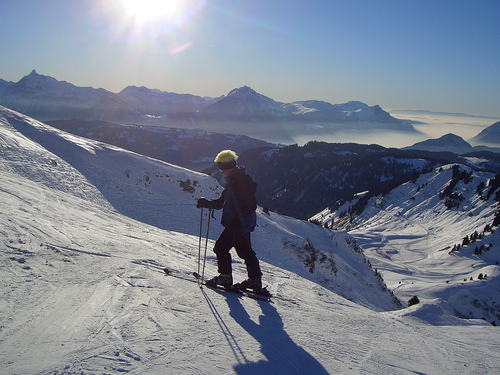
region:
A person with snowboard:
[122, 144, 298, 326]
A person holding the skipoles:
[188, 214, 211, 286]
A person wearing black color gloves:
[192, 190, 220, 215]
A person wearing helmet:
[213, 144, 235, 170]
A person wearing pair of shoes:
[209, 268, 277, 293]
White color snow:
[33, 207, 127, 315]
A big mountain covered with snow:
[319, 106, 486, 266]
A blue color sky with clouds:
[300, 22, 480, 65]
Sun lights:
[115, 0, 221, 42]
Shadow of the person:
[203, 298, 320, 370]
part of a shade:
[248, 306, 273, 356]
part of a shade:
[266, 319, 286, 348]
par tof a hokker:
[163, 181, 255, 303]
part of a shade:
[286, 330, 301, 357]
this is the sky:
[301, 4, 418, 84]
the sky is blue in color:
[382, 11, 473, 65]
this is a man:
[196, 143, 281, 293]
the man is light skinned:
[221, 169, 230, 174]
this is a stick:
[196, 202, 209, 272]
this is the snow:
[38, 240, 125, 327]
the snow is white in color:
[306, 302, 388, 346]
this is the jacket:
[224, 182, 245, 221]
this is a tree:
[303, 138, 340, 191]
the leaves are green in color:
[303, 183, 323, 195]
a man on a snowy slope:
[194, 131, 274, 307]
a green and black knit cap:
[215, 148, 238, 165]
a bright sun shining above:
[102, 4, 222, 56]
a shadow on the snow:
[206, 296, 321, 373]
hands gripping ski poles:
[194, 200, 208, 285]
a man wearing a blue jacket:
[200, 150, 264, 292]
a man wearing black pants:
[190, 146, 274, 308]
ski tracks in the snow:
[380, 222, 432, 287]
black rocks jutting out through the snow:
[440, 169, 497, 211]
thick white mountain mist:
[329, 120, 420, 144]